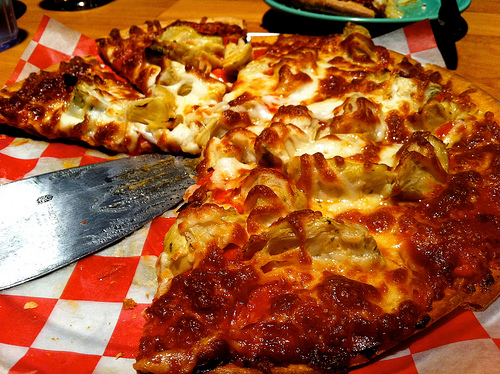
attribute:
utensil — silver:
[4, 154, 196, 271]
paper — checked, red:
[14, 132, 144, 347]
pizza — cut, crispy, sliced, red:
[44, 26, 476, 369]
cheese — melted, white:
[184, 40, 288, 126]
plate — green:
[263, 1, 455, 17]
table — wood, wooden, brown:
[443, 5, 492, 73]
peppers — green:
[243, 201, 405, 278]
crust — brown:
[116, 19, 259, 53]